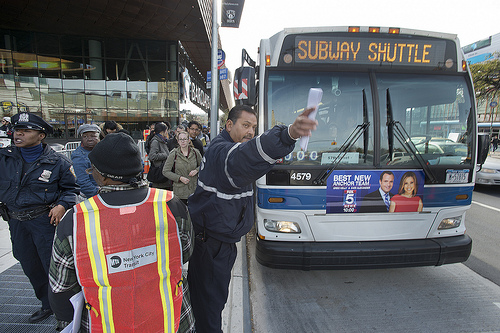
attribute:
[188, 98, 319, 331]
pointing man — pointing right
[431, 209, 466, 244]
headlight — on the left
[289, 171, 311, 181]
number — 4579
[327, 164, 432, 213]
sign — advertisement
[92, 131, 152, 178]
hat — black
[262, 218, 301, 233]
headlight — on the right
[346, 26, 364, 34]
orange light — small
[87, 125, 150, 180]
hat — black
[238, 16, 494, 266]
bus — big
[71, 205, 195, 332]
vest — orange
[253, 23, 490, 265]
bus — blue, white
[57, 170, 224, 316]
vest — orange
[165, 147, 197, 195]
jacket — green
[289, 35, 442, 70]
screen — display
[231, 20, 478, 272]
shuttle bus — subway shuttle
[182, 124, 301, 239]
jacket — blue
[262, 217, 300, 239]
light — on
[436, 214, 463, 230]
light — on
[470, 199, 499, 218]
line — white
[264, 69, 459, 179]
windshield — big